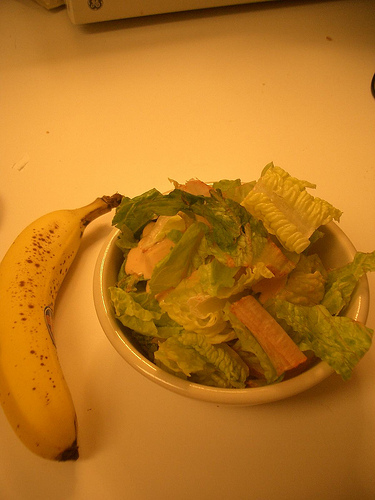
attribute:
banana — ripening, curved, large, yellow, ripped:
[1, 193, 122, 463]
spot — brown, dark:
[30, 350, 38, 356]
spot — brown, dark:
[46, 228, 54, 235]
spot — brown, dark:
[27, 303, 35, 309]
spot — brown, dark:
[31, 385, 38, 393]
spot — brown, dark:
[35, 262, 41, 268]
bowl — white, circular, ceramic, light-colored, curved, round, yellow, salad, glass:
[94, 182, 370, 408]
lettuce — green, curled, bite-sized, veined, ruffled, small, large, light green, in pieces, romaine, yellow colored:
[240, 166, 343, 254]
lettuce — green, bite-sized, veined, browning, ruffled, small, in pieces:
[275, 300, 374, 383]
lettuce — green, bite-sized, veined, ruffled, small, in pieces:
[150, 223, 206, 298]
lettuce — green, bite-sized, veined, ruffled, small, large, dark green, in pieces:
[111, 188, 211, 236]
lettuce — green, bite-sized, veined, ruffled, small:
[153, 337, 207, 377]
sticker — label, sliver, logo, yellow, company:
[42, 307, 56, 350]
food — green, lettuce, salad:
[108, 163, 373, 387]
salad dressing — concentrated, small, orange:
[125, 221, 178, 281]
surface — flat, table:
[1, 27, 374, 163]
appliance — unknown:
[39, 0, 269, 27]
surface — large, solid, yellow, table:
[0, 0, 374, 499]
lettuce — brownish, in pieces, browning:
[229, 295, 309, 374]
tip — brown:
[100, 192, 127, 208]